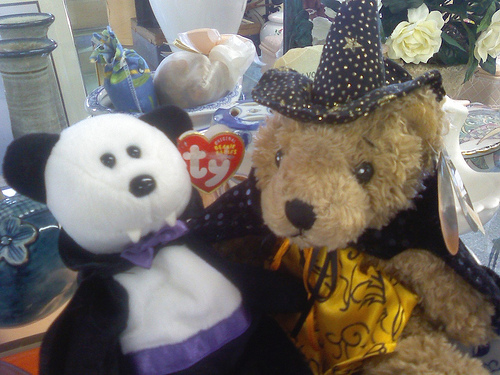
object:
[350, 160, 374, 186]
black eye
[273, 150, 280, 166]
black eye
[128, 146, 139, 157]
black eye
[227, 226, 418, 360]
cloth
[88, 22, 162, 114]
bag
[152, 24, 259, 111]
bag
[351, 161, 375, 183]
eye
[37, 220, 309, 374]
black cape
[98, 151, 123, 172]
eye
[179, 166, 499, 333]
cape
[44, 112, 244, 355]
white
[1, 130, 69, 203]
black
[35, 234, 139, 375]
black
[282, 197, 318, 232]
black nose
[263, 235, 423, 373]
material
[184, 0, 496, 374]
bear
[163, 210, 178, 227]
fang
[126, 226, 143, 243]
fang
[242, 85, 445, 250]
head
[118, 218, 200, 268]
tie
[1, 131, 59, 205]
ear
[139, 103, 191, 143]
ear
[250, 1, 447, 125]
hat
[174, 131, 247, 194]
heart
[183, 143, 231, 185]
ty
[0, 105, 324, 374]
bear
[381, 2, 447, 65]
flower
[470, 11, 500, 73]
flower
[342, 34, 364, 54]
star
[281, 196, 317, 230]
nose